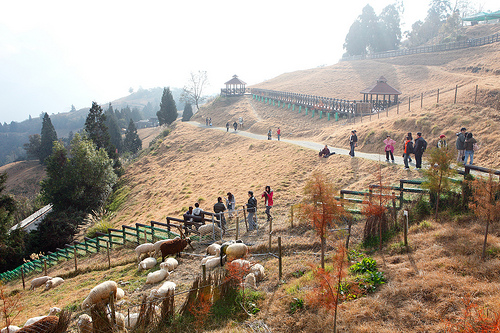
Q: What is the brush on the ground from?
A: Pine trees.